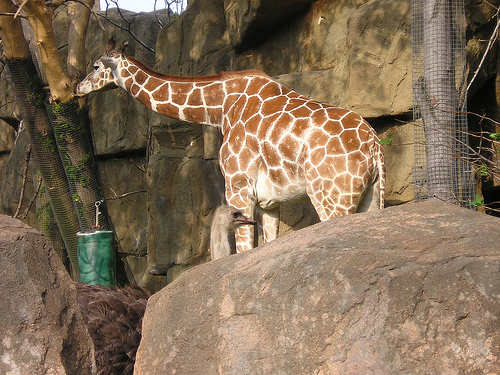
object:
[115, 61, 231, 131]
neck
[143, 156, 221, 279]
rock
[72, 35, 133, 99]
head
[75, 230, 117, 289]
trashcan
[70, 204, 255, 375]
emu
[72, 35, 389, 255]
giraffe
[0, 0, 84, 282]
trunk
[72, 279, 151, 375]
feathers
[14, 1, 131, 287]
tree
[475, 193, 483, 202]
leaf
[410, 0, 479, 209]
mesh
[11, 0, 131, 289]
trunk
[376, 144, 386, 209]
tail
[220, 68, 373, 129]
back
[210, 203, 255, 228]
head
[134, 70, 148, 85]
spot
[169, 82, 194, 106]
spot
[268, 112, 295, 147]
spot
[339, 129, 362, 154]
spot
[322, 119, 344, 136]
spot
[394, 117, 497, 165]
branches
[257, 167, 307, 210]
belly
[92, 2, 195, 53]
tree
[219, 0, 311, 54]
rock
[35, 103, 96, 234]
moss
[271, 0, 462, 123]
rock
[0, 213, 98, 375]
rock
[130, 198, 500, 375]
rocks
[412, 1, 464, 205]
tree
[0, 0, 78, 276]
tree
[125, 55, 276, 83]
mane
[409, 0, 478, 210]
fence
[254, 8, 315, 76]
shadow